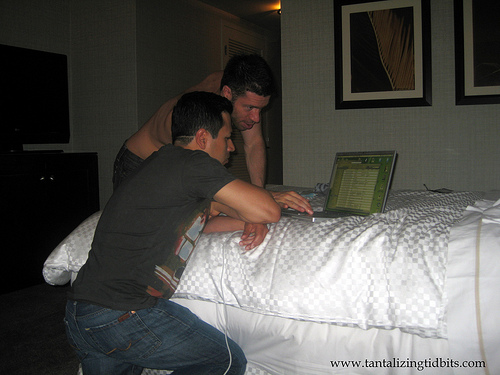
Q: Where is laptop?
A: On bed in photo.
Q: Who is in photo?
A: Two males.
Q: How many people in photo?
A: Two people.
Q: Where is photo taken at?
A: Bedroom.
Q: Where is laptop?
A: On bed.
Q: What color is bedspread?
A: White.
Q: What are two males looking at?
A: Laptop.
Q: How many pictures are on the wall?
A: Two.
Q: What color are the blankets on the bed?
A: White.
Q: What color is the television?
A: Black.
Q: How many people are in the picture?
A: Two.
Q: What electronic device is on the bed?
A: Laptop computer.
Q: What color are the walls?
A: White.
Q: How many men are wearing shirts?
A: One.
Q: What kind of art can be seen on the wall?
A: Abstract.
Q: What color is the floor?
A: Grey.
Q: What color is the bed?
A: White.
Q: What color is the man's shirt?
A: Black.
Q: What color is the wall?
A: White.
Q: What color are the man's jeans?
A: Blue.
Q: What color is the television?
A: Black.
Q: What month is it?
A: November.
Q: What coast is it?
A: East Coast.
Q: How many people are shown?
A: 2.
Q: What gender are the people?
A: Male.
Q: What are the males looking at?
A: Laptop.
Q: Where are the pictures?
A: Wall.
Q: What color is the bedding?
A: White.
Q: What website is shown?
A: Www.tantalizingidbits.com.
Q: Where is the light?
A: Hallway.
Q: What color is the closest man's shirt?
A: Gray.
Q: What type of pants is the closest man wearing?
A: Jeans.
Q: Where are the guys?
A: Bedroom.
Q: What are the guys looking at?
A: Laptop.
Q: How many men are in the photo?
A: Two.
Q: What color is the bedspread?
A: White.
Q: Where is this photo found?
A: www.tantalizingtidbits.com.